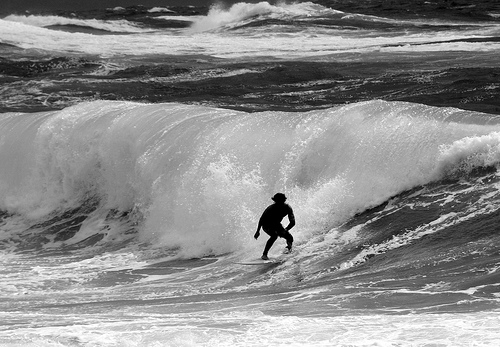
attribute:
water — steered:
[0, 0, 497, 342]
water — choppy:
[352, 217, 475, 309]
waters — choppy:
[2, 99, 492, 261]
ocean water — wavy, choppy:
[3, 3, 495, 345]